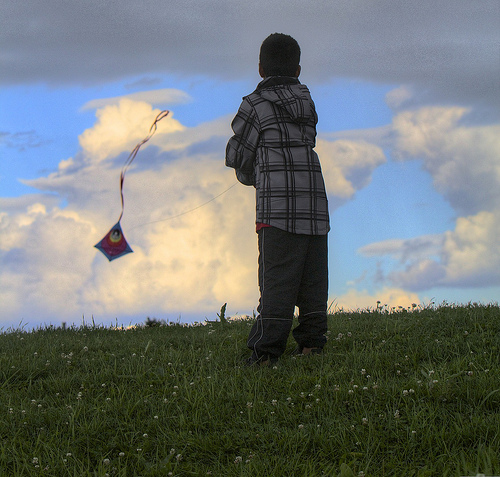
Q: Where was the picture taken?
A: Outside on a hill.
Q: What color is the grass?
A: Green.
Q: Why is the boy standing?
A: To fly the kite.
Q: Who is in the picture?
A: A boy.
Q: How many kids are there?
A: 1.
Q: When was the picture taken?
A: In the daytime.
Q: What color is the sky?
A: Blue.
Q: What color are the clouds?
A: White.